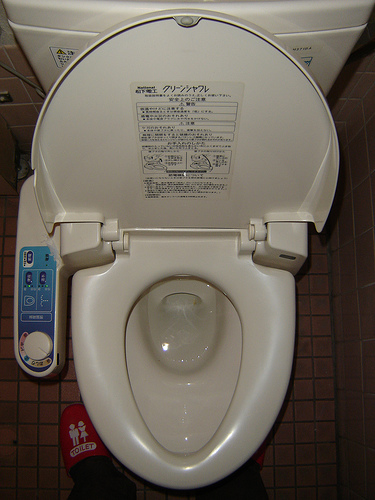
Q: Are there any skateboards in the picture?
A: No, there are no skateboards.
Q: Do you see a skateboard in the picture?
A: No, there are no skateboards.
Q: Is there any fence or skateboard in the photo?
A: No, there are no skateboards or fences.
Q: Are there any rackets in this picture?
A: No, there are no rackets.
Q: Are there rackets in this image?
A: No, there are no rackets.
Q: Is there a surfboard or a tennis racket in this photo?
A: No, there are no rackets or surfboards.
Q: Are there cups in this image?
A: Yes, there is a cup.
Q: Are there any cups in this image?
A: Yes, there is a cup.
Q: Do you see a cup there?
A: Yes, there is a cup.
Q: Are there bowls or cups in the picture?
A: Yes, there is a cup.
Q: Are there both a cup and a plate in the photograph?
A: No, there is a cup but no plates.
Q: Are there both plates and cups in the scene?
A: No, there is a cup but no plates.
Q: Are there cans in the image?
A: No, there are no cans.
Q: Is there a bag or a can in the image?
A: No, there are no cans or bags.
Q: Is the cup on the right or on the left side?
A: The cup is on the left of the image.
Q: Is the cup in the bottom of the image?
A: Yes, the cup is in the bottom of the image.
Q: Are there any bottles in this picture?
A: No, there are no bottles.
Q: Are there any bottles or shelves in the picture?
A: No, there are no bottles or shelves.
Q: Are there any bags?
A: No, there are no bags.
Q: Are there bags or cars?
A: No, there are no bags or cars.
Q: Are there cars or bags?
A: No, there are no bags or cars.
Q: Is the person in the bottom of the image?
A: Yes, the person is in the bottom of the image.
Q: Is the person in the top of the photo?
A: No, the person is in the bottom of the image.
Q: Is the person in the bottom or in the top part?
A: The person is in the bottom of the image.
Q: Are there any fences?
A: No, there are no fences.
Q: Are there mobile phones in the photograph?
A: No, there are no mobile phones.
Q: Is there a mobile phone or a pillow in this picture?
A: No, there are no cell phones or pillows.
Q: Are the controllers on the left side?
A: Yes, the controllers are on the left of the image.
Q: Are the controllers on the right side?
A: No, the controllers are on the left of the image.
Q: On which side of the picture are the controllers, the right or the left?
A: The controllers are on the left of the image.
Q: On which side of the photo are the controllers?
A: The controllers are on the left of the image.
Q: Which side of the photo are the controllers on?
A: The controllers are on the left of the image.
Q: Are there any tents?
A: No, there are no tents.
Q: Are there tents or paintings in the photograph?
A: No, there are no tents or paintings.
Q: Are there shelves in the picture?
A: No, there are no shelves.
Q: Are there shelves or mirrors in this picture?
A: No, there are no shelves or mirrors.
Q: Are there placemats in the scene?
A: No, there are no placemats.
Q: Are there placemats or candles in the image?
A: No, there are no placemats or candles.